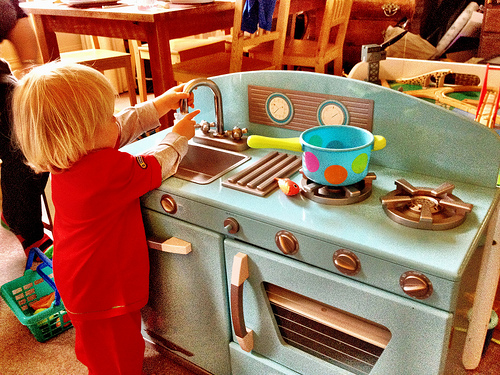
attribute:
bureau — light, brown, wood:
[303, 0, 421, 63]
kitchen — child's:
[130, 69, 498, 369]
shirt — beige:
[112, 95, 189, 182]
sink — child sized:
[157, 129, 252, 188]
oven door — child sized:
[214, 230, 467, 373]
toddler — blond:
[7, 42, 239, 369]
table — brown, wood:
[22, 0, 242, 102]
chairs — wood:
[9, 2, 350, 99]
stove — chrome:
[109, 36, 483, 371]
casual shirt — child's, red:
[34, 159, 131, 310]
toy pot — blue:
[241, 122, 388, 189]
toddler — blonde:
[5, 58, 211, 371]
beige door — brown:
[106, 84, 324, 349]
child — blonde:
[11, 62, 197, 372]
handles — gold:
[381, 0, 404, 19]